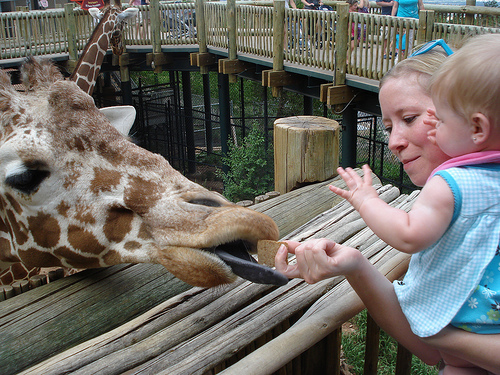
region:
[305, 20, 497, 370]
A WOMAN HOLDING A BABY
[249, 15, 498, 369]
A WOMAN FEEDING A GIRAFFE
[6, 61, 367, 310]
A GIRAFFE BEING FED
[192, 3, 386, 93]
A WOODEN FENCE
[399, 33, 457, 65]
A PAIR OF SUNGLASSES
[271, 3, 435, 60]
PEOPLE IN THE BACKGROUND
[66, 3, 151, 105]
A GIRAFFE IN THE BACKGROUND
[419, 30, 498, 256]
A BABY WEARING A PINK BIB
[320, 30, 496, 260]
A BABY TOUCHING IT'S MOM'S FACE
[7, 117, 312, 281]
A TREAT FOR THE GIRAFFE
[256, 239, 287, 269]
a snack for the giraffe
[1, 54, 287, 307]
a giraffe's head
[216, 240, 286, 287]
the black tongue of the giraffe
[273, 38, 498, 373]
a woman feeding the giraffe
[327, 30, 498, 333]
a baby being held by the woman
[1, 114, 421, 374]
a wooden fence between the people and the giraffe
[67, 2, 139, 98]
another giraffe in the background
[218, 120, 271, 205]
a small tree under the deck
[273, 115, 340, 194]
a wooden post on the fence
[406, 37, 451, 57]
blue sunglasses on the woman's head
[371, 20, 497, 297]
Baby in mommy's arms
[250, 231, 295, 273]
Cracker for a giraffe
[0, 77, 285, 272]
Giraffe up close and personal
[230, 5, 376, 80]
Wooden fence posts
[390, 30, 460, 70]
Light blue sunglasses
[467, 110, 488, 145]
Baby's pierced ear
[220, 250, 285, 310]
Black giraffe tongue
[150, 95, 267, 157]
Black metal fence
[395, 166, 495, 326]
Baby Blue checker patterned Baby dress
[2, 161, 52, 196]
Up close picture of a giraffe's eyeball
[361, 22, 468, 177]
Blue glasses on the woman's head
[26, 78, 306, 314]
Giraffe eating a cracker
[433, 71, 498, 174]
baby wearing earring stud in ear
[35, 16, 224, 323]
Two giraffes in enclosure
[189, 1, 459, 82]
wood railing on board walk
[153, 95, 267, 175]
enclosure fencing under the boardwalk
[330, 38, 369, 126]
Power conduit under the board walk.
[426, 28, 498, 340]
Baby wearing blue dress and pink bib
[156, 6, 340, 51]
three baby stollers on the board walk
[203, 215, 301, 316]
giraffe's long black tongue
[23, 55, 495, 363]
woman is feeding the giraffe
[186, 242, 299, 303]
giraffe's tongue is black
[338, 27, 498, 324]
woman is carrying a baby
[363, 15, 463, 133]
the sunglass is blue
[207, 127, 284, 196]
the bush is green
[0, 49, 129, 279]
the eye is black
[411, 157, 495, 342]
the dress is blue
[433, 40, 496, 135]
the baby is blonde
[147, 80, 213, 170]
the fence is black